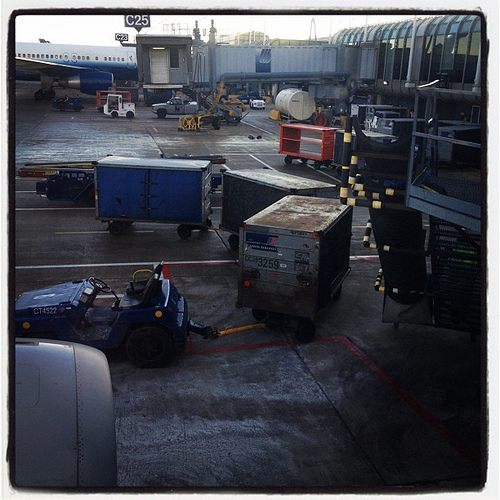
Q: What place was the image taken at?
A: It was taken at the airport.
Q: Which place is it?
A: It is an airport.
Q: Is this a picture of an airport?
A: Yes, it is showing an airport.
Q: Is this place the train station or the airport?
A: It is the airport.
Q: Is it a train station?
A: No, it is an airport.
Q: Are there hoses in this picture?
A: No, there are no hoses.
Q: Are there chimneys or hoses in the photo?
A: No, there are no hoses or chimneys.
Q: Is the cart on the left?
A: Yes, the cart is on the left of the image.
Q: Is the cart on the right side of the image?
A: No, the cart is on the left of the image.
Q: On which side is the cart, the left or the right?
A: The cart is on the left of the image.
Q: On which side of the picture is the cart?
A: The cart is on the left of the image.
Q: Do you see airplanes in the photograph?
A: Yes, there is an airplane.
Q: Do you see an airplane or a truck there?
A: Yes, there is an airplane.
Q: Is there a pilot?
A: No, there are no pilots.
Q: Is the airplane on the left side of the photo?
A: Yes, the airplane is on the left of the image.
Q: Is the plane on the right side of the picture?
A: No, the plane is on the left of the image.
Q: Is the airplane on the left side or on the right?
A: The airplane is on the left of the image.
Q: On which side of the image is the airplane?
A: The airplane is on the left of the image.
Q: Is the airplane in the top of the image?
A: Yes, the airplane is in the top of the image.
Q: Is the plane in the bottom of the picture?
A: No, the plane is in the top of the image.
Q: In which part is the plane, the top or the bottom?
A: The plane is in the top of the image.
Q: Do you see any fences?
A: No, there are no fences.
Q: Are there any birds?
A: No, there are no birds.